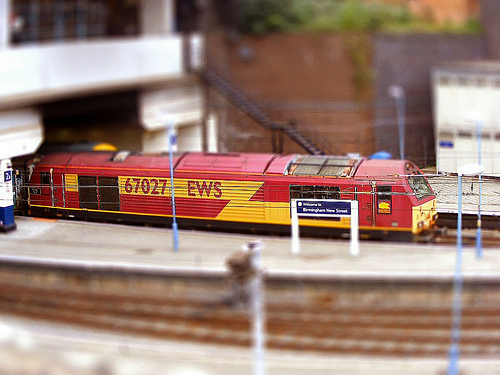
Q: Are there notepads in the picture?
A: No, there are no notepads.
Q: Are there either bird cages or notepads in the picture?
A: No, there are no notepads or bird cages.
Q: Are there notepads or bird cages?
A: No, there are no notepads or bird cages.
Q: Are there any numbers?
A: Yes, there are numbers.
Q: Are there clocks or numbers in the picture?
A: Yes, there are numbers.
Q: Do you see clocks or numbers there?
A: Yes, there are numbers.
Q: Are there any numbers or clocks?
A: Yes, there are numbers.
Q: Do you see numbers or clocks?
A: Yes, there are numbers.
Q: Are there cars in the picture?
A: No, there are no cars.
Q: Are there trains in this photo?
A: Yes, there is a train.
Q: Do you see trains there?
A: Yes, there is a train.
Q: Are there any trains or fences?
A: Yes, there is a train.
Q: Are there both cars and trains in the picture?
A: No, there is a train but no cars.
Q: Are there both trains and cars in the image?
A: No, there is a train but no cars.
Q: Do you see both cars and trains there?
A: No, there is a train but no cars.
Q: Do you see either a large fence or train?
A: Yes, there is a large train.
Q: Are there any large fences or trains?
A: Yes, there is a large train.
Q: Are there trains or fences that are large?
A: Yes, the train is large.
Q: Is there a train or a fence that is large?
A: Yes, the train is large.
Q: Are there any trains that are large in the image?
A: Yes, there is a large train.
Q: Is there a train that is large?
A: Yes, there is a train that is large.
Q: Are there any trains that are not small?
A: Yes, there is a large train.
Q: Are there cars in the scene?
A: No, there are no cars.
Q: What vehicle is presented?
A: The vehicle is a train.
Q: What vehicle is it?
A: The vehicle is a train.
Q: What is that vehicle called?
A: This is a train.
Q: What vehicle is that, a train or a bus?
A: This is a train.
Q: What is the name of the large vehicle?
A: The vehicle is a train.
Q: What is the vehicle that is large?
A: The vehicle is a train.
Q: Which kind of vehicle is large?
A: The vehicle is a train.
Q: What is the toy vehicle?
A: The vehicle is a train.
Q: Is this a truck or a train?
A: This is a train.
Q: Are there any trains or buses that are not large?
A: No, there is a train but it is large.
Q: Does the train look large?
A: Yes, the train is large.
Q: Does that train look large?
A: Yes, the train is large.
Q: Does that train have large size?
A: Yes, the train is large.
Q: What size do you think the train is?
A: The train is large.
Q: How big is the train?
A: The train is large.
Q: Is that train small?
A: No, the train is large.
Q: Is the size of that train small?
A: No, the train is large.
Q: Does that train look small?
A: No, the train is large.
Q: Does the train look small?
A: No, the train is large.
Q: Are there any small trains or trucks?
A: No, there is a train but it is large.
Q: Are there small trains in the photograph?
A: No, there is a train but it is large.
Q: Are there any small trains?
A: No, there is a train but it is large.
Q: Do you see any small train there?
A: No, there is a train but it is large.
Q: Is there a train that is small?
A: No, there is a train but it is large.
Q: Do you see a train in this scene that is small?
A: No, there is a train but it is large.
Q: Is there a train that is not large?
A: No, there is a train but it is large.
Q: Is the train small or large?
A: The train is large.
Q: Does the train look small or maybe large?
A: The train is large.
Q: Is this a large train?
A: Yes, this is a large train.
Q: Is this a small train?
A: No, this is a large train.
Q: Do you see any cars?
A: No, there are no cars.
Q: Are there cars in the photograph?
A: No, there are no cars.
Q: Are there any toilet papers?
A: No, there are no toilet papers.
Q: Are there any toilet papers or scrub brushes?
A: No, there are no toilet papers or scrub brushes.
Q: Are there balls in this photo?
A: No, there are no balls.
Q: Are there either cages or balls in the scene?
A: No, there are no balls or cages.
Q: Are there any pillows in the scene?
A: No, there are no pillows.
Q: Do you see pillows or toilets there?
A: No, there are no pillows or toilets.